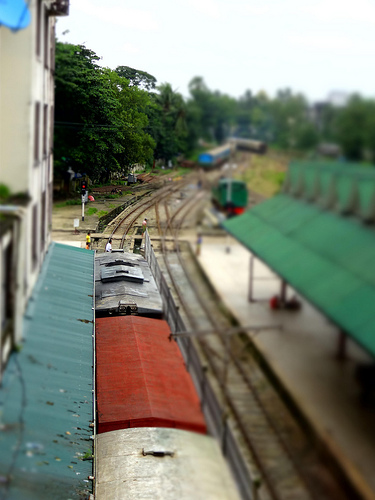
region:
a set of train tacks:
[90, 165, 183, 241]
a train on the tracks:
[64, 215, 256, 498]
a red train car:
[90, 292, 208, 473]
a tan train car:
[82, 410, 242, 496]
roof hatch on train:
[94, 242, 162, 302]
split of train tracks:
[146, 201, 205, 257]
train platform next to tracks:
[188, 218, 368, 487]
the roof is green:
[27, 233, 89, 469]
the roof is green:
[27, 238, 107, 463]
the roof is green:
[16, 217, 91, 443]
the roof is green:
[16, 220, 87, 418]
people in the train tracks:
[75, 224, 143, 254]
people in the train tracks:
[69, 215, 129, 255]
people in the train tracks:
[67, 220, 138, 274]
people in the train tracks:
[78, 224, 133, 263]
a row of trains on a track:
[91, 236, 248, 498]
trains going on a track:
[185, 112, 270, 205]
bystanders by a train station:
[75, 214, 189, 257]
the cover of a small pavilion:
[221, 158, 374, 387]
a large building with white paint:
[1, 3, 97, 483]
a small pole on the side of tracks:
[75, 181, 141, 227]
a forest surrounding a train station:
[56, 50, 371, 198]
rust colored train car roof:
[93, 291, 215, 446]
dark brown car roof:
[87, 240, 164, 327]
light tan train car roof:
[81, 418, 242, 490]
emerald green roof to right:
[225, 152, 373, 336]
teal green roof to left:
[8, 242, 111, 483]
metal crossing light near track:
[64, 171, 97, 219]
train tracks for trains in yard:
[127, 182, 207, 240]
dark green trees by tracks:
[61, 55, 184, 170]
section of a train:
[83, 244, 174, 309]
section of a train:
[85, 298, 187, 391]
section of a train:
[82, 346, 220, 442]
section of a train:
[92, 387, 232, 492]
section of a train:
[96, 431, 247, 498]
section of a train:
[195, 136, 246, 182]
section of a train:
[231, 130, 264, 166]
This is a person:
[99, 233, 122, 264]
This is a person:
[85, 229, 99, 255]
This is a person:
[134, 212, 155, 241]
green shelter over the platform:
[226, 156, 373, 345]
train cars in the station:
[94, 245, 239, 497]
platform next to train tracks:
[194, 231, 368, 488]